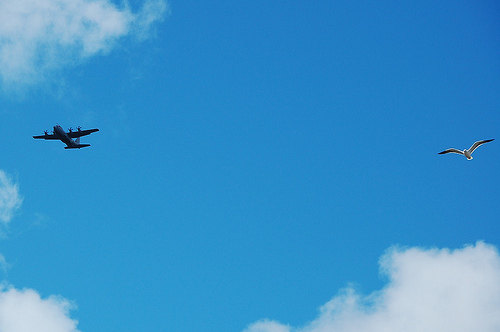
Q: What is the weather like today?
A: It is clear.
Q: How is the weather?
A: It is clear.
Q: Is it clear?
A: Yes, it is clear.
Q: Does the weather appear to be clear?
A: Yes, it is clear.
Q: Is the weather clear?
A: Yes, it is clear.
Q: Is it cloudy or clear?
A: It is clear.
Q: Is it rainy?
A: No, it is clear.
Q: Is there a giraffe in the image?
A: No, there are no giraffes.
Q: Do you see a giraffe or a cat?
A: No, there are no giraffes or cats.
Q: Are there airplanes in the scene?
A: Yes, there is an airplane.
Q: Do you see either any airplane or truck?
A: Yes, there is an airplane.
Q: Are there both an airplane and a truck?
A: No, there is an airplane but no trucks.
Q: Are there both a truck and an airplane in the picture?
A: No, there is an airplane but no trucks.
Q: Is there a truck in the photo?
A: No, there are no trucks.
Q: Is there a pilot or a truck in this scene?
A: No, there are no trucks or pilots.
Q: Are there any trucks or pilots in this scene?
A: No, there are no trucks or pilots.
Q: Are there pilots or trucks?
A: No, there are no trucks or pilots.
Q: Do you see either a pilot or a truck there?
A: No, there are no trucks or pilots.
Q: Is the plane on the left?
A: Yes, the plane is on the left of the image.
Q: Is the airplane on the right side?
A: No, the airplane is on the left of the image.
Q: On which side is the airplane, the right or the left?
A: The airplane is on the left of the image.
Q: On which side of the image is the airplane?
A: The airplane is on the left of the image.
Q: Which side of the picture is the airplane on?
A: The airplane is on the left of the image.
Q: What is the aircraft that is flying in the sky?
A: The aircraft is an airplane.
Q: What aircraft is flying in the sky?
A: The aircraft is an airplane.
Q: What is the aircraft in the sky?
A: The aircraft is an airplane.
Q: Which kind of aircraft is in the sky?
A: The aircraft is an airplane.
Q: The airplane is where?
A: The airplane is in the sky.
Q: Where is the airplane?
A: The airplane is in the sky.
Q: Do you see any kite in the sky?
A: No, there is an airplane in the sky.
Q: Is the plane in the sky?
A: Yes, the plane is in the sky.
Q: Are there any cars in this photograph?
A: No, there are no cars.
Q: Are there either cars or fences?
A: No, there are no cars or fences.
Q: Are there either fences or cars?
A: No, there are no cars or fences.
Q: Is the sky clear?
A: Yes, the sky is clear.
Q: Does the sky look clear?
A: Yes, the sky is clear.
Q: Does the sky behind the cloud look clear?
A: Yes, the sky is clear.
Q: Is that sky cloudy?
A: No, the sky is clear.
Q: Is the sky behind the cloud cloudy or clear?
A: The sky is clear.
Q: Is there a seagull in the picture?
A: Yes, there is a seagull.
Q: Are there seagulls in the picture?
A: Yes, there is a seagull.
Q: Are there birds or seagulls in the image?
A: Yes, there is a seagull.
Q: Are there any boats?
A: No, there are no boats.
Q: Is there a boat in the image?
A: No, there are no boats.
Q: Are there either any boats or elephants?
A: No, there are no boats or elephants.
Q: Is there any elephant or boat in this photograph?
A: No, there are no boats or elephants.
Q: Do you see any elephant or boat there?
A: No, there are no boats or elephants.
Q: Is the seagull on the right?
A: Yes, the seagull is on the right of the image.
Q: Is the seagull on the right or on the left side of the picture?
A: The seagull is on the right of the image.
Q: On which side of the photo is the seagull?
A: The seagull is on the right of the image.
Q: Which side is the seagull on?
A: The seagull is on the right of the image.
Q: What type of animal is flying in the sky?
A: The animal is a seagull.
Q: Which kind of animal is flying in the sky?
A: The animal is a seagull.